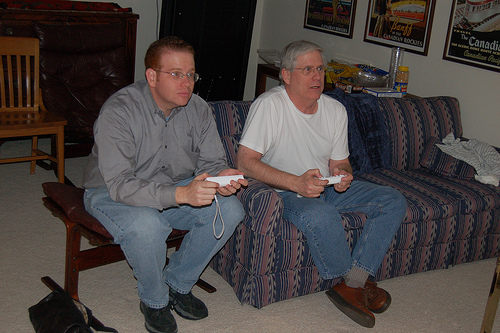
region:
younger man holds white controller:
[207, 171, 253, 203]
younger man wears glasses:
[158, 61, 210, 103]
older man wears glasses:
[288, 60, 343, 86]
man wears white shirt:
[242, 83, 353, 174]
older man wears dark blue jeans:
[280, 173, 387, 278]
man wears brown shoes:
[308, 266, 398, 306]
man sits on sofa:
[245, 88, 475, 305]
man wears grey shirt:
[70, 70, 219, 195]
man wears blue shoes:
[88, 285, 223, 332]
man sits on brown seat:
[33, 154, 150, 304]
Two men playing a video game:
[82, 33, 410, 331]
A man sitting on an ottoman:
[32, 38, 228, 331]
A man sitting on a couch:
[234, 35, 425, 327]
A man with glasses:
[138, 29, 201, 119]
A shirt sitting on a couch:
[419, 114, 499, 182]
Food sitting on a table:
[250, 31, 420, 110]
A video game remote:
[174, 161, 249, 204]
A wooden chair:
[2, 28, 73, 195]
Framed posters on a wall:
[298, 1, 498, 88]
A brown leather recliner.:
[32, 20, 165, 168]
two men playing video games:
[97, 23, 412, 326]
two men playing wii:
[71, 27, 401, 307]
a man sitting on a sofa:
[200, 37, 495, 312]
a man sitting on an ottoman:
[85, 15, 240, 320]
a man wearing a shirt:
[55, 35, 250, 210]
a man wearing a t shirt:
[225, 27, 395, 203]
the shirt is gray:
[71, 77, 236, 203]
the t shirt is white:
[237, 85, 357, 195]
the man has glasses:
[112, 33, 218, 114]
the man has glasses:
[262, 39, 337, 112]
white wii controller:
[200, 172, 251, 192]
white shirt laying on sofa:
[440, 125, 495, 190]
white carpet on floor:
[412, 285, 462, 330]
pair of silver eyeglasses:
[152, 62, 202, 82]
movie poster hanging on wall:
[436, 0, 496, 70]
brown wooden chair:
[0, 35, 65, 172]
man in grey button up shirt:
[65, 40, 240, 312]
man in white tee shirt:
[251, 40, 421, 311]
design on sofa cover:
[421, 183, 463, 242]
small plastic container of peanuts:
[395, 64, 411, 96]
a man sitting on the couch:
[233, 32, 425, 329]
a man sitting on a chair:
[76, 12, 265, 330]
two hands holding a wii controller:
[175, 155, 266, 245]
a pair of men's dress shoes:
[318, 264, 403, 331]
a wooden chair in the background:
[6, 22, 78, 187]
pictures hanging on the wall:
[293, 9, 485, 54]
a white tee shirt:
[233, 85, 363, 185]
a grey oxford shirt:
[79, 72, 210, 205]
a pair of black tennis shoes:
[133, 282, 215, 332]